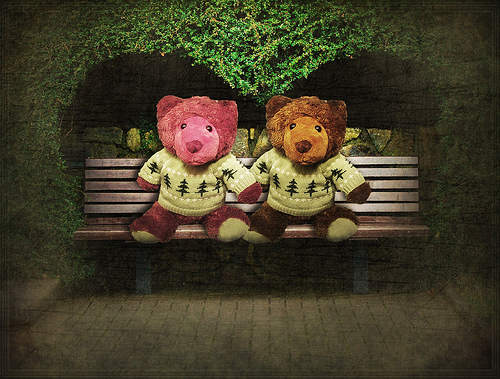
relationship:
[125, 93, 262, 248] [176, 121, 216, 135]
teddy bear has eyes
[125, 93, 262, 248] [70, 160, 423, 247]
teddy bear on bench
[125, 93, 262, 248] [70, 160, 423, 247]
teddy bear on a bench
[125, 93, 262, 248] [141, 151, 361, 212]
teddy bear in shirt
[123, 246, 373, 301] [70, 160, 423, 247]
leg under bench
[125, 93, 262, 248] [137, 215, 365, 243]
teddy bear has feet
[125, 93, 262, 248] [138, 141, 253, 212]
teddy bear wearing sweater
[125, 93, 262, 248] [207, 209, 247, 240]
teddy bear has foot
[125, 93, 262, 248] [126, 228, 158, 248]
teddy bear has foot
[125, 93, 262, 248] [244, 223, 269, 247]
teddy bear has foot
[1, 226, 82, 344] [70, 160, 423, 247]
steps at side of bench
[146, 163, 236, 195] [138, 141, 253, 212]
tree design on sweater